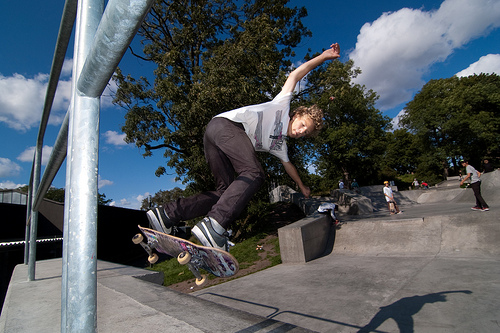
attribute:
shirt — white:
[213, 94, 290, 162]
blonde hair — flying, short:
[293, 103, 323, 131]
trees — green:
[113, 4, 499, 178]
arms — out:
[281, 42, 341, 200]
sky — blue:
[1, 0, 499, 169]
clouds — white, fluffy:
[337, 2, 499, 110]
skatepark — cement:
[0, 190, 499, 330]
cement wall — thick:
[268, 184, 333, 265]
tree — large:
[112, 5, 310, 195]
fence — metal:
[25, 2, 154, 332]